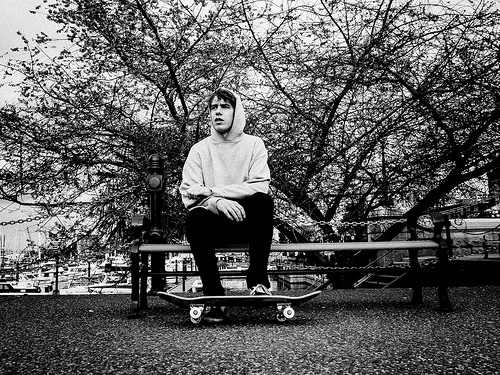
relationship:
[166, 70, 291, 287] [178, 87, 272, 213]
man wears jacket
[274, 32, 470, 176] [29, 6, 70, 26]
trees have no leaves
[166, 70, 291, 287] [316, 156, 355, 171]
man looking to right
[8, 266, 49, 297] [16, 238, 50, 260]
boat in background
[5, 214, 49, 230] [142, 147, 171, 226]
chain tied to post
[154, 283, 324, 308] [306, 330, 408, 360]
skateboard on ground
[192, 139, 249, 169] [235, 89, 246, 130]
jacket has hood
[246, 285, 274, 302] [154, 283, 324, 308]
feet resting on skateboard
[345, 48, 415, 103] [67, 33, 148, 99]
branches of a tree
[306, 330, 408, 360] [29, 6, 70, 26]
ground covered in leaves